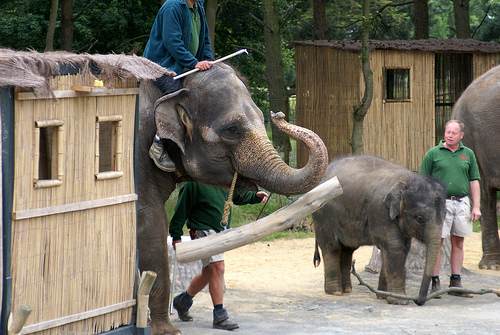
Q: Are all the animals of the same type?
A: Yes, all the animals are elephants.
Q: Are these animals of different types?
A: No, all the animals are elephants.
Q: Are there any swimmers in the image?
A: No, there are no swimmers.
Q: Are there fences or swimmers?
A: No, there are no swimmers or fences.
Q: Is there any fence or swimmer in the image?
A: No, there are no swimmers or fences.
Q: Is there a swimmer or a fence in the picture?
A: No, there are no swimmers or fences.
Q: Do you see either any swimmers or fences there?
A: No, there are no swimmers or fences.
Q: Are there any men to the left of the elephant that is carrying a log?
A: Yes, there is a man to the left of the elephant.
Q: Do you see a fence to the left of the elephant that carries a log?
A: No, there is a man to the left of the elephant.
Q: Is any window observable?
A: Yes, there is a window.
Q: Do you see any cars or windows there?
A: Yes, there is a window.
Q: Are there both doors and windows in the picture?
A: No, there is a window but no doors.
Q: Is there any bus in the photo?
A: No, there are no buses.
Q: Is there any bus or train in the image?
A: No, there are no buses or trains.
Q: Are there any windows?
A: Yes, there is a window.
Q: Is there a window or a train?
A: Yes, there is a window.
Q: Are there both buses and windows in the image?
A: No, there is a window but no buses.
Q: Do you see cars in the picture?
A: No, there are no cars.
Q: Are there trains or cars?
A: No, there are no cars or trains.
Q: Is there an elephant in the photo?
A: Yes, there is an elephant.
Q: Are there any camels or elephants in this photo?
A: Yes, there is an elephant.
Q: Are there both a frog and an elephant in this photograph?
A: No, there is an elephant but no frogs.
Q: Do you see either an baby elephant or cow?
A: Yes, there is a baby elephant.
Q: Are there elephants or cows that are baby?
A: Yes, the elephant is a baby.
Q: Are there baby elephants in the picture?
A: Yes, there is a baby elephant.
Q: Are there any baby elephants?
A: Yes, there is a baby elephant.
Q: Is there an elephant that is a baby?
A: Yes, there is an elephant that is a baby.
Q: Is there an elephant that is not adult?
A: Yes, there is an baby elephant.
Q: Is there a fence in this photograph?
A: No, there are no fences.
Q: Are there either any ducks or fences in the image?
A: No, there are no fences or ducks.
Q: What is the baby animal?
A: The animal is an elephant.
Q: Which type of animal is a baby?
A: The animal is an elephant.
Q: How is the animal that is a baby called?
A: The animal is an elephant.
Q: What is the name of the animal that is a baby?
A: The animal is an elephant.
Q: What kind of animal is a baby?
A: The animal is an elephant.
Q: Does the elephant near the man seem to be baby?
A: Yes, the elephant is a baby.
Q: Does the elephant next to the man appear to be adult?
A: No, the elephant is a baby.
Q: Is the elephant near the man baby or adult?
A: The elephant is a baby.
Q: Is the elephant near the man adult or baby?
A: The elephant is a baby.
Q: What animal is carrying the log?
A: The elephant is carrying the log.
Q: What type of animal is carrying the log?
A: The animal is an elephant.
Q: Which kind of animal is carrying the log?
A: The animal is an elephant.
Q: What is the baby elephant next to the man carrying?
A: The elephant is carrying a log.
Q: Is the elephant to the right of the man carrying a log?
A: Yes, the elephant is carrying a log.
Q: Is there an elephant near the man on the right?
A: Yes, there is an elephant near the man.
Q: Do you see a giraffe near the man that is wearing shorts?
A: No, there is an elephant near the man.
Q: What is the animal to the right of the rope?
A: The animal is an elephant.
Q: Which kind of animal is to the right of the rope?
A: The animal is an elephant.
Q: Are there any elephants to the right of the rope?
A: Yes, there is an elephant to the right of the rope.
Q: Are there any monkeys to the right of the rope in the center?
A: No, there is an elephant to the right of the rope.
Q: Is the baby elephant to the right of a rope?
A: Yes, the elephant is to the right of a rope.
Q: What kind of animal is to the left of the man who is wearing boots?
A: The animal is an elephant.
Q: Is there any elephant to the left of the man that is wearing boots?
A: Yes, there is an elephant to the left of the man.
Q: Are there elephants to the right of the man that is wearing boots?
A: No, the elephant is to the left of the man.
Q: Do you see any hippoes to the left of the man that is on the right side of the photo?
A: No, there is an elephant to the left of the man.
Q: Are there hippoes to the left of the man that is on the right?
A: No, there is an elephant to the left of the man.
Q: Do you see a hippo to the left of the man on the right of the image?
A: No, there is an elephant to the left of the man.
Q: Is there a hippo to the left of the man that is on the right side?
A: No, there is an elephant to the left of the man.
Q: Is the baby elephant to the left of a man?
A: Yes, the elephant is to the left of a man.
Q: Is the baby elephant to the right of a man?
A: No, the elephant is to the left of a man.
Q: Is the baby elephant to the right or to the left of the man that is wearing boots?
A: The elephant is to the left of the man.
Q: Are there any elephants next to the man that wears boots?
A: Yes, there is an elephant next to the man.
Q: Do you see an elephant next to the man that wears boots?
A: Yes, there is an elephant next to the man.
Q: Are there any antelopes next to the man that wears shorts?
A: No, there is an elephant next to the man.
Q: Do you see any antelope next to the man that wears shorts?
A: No, there is an elephant next to the man.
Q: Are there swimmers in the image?
A: No, there are no swimmers.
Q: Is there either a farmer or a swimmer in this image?
A: No, there are no swimmers or farmers.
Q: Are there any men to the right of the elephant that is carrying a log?
A: Yes, there is a man to the right of the elephant.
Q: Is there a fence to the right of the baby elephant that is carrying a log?
A: No, there is a man to the right of the elephant.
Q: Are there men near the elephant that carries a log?
A: Yes, there is a man near the elephant.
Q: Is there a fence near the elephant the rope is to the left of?
A: No, there is a man near the elephant.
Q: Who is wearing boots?
A: The man is wearing boots.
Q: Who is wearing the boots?
A: The man is wearing boots.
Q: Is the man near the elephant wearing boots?
A: Yes, the man is wearing boots.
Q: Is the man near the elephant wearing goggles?
A: No, the man is wearing boots.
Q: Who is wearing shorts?
A: The man is wearing shorts.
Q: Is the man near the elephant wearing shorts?
A: Yes, the man is wearing shorts.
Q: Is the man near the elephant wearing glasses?
A: No, the man is wearing shorts.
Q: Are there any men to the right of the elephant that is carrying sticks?
A: Yes, there is a man to the right of the elephant.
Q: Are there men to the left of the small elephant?
A: No, the man is to the right of the elephant.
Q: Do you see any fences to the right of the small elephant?
A: No, there is a man to the right of the elephant.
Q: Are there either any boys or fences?
A: No, there are no boys or fences.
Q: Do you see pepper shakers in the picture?
A: No, there are no pepper shakers.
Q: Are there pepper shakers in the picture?
A: No, there are no pepper shakers.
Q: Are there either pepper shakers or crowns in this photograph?
A: No, there are no pepper shakers or crowns.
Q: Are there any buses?
A: No, there are no buses.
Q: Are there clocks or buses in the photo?
A: No, there are no buses or clocks.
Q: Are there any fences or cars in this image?
A: No, there are no fences or cars.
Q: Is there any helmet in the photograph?
A: No, there are no helmets.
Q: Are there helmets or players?
A: No, there are no helmets or players.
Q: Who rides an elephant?
A: The man rides an elephant.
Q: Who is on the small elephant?
A: The man is on the elephant.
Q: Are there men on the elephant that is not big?
A: Yes, there is a man on the elephant.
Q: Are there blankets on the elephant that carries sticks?
A: No, there is a man on the elephant.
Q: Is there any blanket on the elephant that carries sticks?
A: No, there is a man on the elephant.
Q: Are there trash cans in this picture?
A: No, there are no trash cans.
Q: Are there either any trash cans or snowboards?
A: No, there are no trash cans or snowboards.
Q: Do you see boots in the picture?
A: Yes, there are boots.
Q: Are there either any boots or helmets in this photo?
A: Yes, there are boots.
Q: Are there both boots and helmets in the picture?
A: No, there are boots but no helmets.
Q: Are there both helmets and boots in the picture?
A: No, there are boots but no helmets.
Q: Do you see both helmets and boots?
A: No, there are boots but no helmets.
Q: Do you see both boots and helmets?
A: No, there are boots but no helmets.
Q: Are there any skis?
A: No, there are no skis.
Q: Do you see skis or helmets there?
A: No, there are no skis or helmets.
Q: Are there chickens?
A: No, there are no chickens.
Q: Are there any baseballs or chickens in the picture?
A: No, there are no chickens or baseballs.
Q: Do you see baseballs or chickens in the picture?
A: No, there are no chickens or baseballs.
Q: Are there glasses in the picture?
A: No, there are no glasses.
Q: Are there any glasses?
A: No, there are no glasses.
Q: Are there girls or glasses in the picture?
A: No, there are no glasses or girls.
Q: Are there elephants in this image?
A: Yes, there is an elephant.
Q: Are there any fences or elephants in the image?
A: Yes, there is an elephant.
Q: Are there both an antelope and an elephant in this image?
A: No, there is an elephant but no antelopes.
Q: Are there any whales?
A: No, there are no whales.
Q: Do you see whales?
A: No, there are no whales.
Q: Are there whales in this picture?
A: No, there are no whales.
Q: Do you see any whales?
A: No, there are no whales.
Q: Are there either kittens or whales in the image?
A: No, there are no whales or kittens.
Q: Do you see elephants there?
A: Yes, there is an elephant.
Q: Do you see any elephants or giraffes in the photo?
A: Yes, there is an elephant.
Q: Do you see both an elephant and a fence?
A: No, there is an elephant but no fences.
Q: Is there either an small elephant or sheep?
A: Yes, there is a small elephant.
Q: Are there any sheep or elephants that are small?
A: Yes, the elephant is small.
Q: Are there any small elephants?
A: Yes, there is a small elephant.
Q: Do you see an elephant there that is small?
A: Yes, there is an elephant that is small.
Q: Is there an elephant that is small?
A: Yes, there is an elephant that is small.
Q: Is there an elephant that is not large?
A: Yes, there is a small elephant.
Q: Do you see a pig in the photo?
A: No, there are no pigs.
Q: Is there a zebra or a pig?
A: No, there are no pigs or zebras.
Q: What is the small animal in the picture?
A: The animal is an elephant.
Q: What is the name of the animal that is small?
A: The animal is an elephant.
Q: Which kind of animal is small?
A: The animal is an elephant.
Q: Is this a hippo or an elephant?
A: This is an elephant.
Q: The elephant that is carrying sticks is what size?
A: The elephant is small.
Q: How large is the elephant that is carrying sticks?
A: The elephant is small.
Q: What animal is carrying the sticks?
A: The elephant is carrying the sticks.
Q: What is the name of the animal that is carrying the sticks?
A: The animal is an elephant.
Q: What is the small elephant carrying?
A: The elephant is carrying sticks.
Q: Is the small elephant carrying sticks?
A: Yes, the elephant is carrying sticks.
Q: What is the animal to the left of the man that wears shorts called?
A: The animal is an elephant.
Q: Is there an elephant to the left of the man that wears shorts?
A: Yes, there is an elephant to the left of the man.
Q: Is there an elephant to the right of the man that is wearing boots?
A: No, the elephant is to the left of the man.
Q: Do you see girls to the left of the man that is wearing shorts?
A: No, there is an elephant to the left of the man.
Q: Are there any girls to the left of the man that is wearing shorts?
A: No, there is an elephant to the left of the man.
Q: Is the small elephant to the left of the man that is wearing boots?
A: Yes, the elephant is to the left of the man.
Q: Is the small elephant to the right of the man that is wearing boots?
A: No, the elephant is to the left of the man.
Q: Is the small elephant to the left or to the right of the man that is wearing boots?
A: The elephant is to the left of the man.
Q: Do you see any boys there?
A: No, there are no boys.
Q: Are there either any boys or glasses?
A: No, there are no boys or glasses.